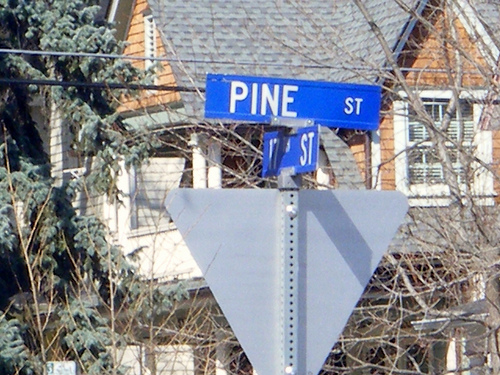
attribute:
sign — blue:
[262, 123, 318, 178]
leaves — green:
[2, 2, 192, 372]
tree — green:
[2, 0, 190, 371]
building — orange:
[102, 1, 498, 371]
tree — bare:
[1, 0, 498, 371]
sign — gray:
[162, 188, 407, 373]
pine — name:
[230, 80, 299, 117]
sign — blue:
[203, 72, 378, 131]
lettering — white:
[227, 80, 362, 117]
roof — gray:
[102, 1, 499, 126]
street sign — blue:
[202, 74, 381, 130]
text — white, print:
[229, 78, 363, 118]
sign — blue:
[201, 70, 384, 176]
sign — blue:
[256, 136, 321, 166]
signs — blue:
[199, 71, 385, 177]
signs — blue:
[200, 62, 399, 195]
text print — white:
[216, 79, 367, 126]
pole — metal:
[270, 185, 308, 373]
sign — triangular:
[167, 175, 412, 373]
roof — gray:
[223, 21, 338, 70]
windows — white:
[403, 93, 488, 198]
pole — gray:
[278, 194, 298, 373]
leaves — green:
[6, 11, 149, 94]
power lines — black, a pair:
[3, 46, 496, 108]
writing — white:
[228, 76, 362, 122]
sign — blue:
[207, 68, 381, 171]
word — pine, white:
[227, 80, 299, 125]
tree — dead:
[316, 3, 498, 371]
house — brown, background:
[46, 0, 499, 372]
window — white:
[392, 90, 484, 211]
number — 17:
[261, 133, 283, 166]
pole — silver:
[280, 186, 310, 371]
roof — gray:
[136, 5, 496, 193]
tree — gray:
[370, 11, 499, 372]